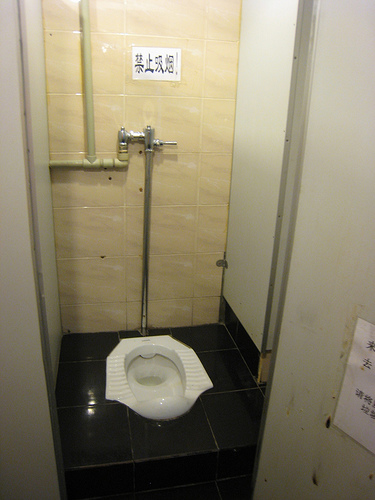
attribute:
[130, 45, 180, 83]
sign — white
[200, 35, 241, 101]
tile — white, stone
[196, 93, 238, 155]
tile — white, stone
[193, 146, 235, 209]
tile — white, stone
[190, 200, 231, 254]
tile — white, stone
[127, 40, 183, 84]
sign — asian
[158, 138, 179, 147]
handle — is silver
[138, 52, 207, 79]
lettering — black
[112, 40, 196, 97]
sign — white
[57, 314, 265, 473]
flooring — is black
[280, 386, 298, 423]
mark — rust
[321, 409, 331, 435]
mark — rust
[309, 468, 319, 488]
mark — rust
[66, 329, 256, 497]
floor — black, tiled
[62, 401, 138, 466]
tile — black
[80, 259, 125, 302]
tile — yellow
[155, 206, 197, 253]
tile — yellow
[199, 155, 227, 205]
tile — yellow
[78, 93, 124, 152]
tile — yellow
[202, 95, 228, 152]
tile — yellow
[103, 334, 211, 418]
seat — toilet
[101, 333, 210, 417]
toilet — white, porcelain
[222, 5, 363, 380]
wall — white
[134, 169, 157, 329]
piping — is silver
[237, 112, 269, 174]
walls — white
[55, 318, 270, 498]
floor — is black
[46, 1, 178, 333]
plumbing — exposed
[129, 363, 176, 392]
water — clear